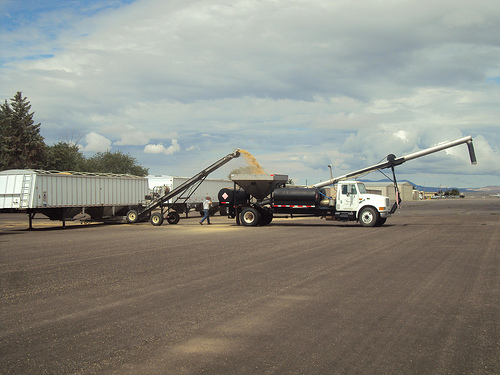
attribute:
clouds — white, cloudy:
[41, 1, 499, 135]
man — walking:
[199, 194, 214, 226]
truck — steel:
[228, 171, 395, 227]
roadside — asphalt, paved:
[0, 231, 499, 374]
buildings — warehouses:
[366, 179, 423, 200]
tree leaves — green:
[0, 92, 149, 175]